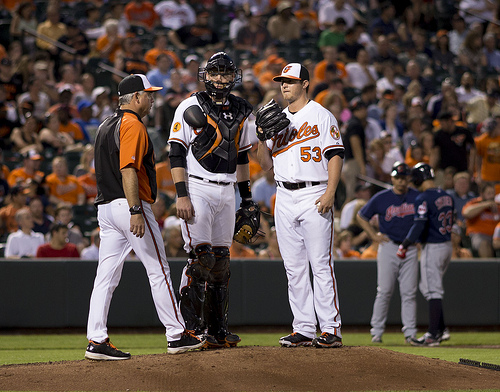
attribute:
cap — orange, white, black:
[273, 61, 310, 81]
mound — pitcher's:
[2, 346, 499, 392]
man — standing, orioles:
[85, 73, 207, 361]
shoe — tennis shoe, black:
[84, 338, 131, 361]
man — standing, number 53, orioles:
[255, 62, 346, 350]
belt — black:
[276, 181, 320, 190]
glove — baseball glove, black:
[255, 99, 291, 142]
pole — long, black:
[21, 27, 393, 189]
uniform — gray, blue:
[358, 190, 419, 338]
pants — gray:
[370, 242, 419, 338]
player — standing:
[167, 51, 260, 348]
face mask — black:
[197, 52, 243, 99]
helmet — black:
[410, 162, 435, 187]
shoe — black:
[166, 331, 206, 354]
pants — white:
[274, 180, 342, 340]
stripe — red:
[328, 212, 341, 337]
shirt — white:
[265, 99, 345, 183]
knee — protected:
[197, 245, 215, 273]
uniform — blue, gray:
[396, 188, 456, 348]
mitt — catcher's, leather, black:
[235, 203, 272, 245]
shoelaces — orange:
[107, 341, 118, 350]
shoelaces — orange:
[185, 328, 203, 344]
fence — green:
[0, 259, 499, 327]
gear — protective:
[184, 51, 253, 347]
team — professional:
[85, 51, 344, 361]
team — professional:
[356, 161, 455, 347]